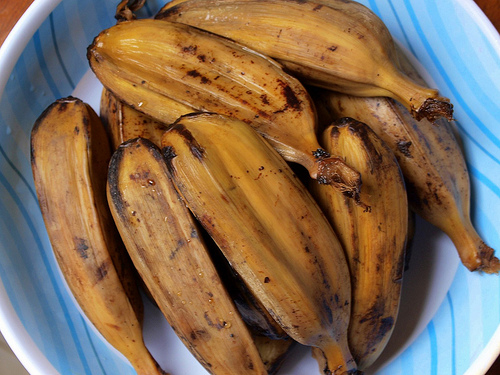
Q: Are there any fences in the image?
A: No, there are no fences.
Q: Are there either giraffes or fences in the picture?
A: No, there are no fences or giraffes.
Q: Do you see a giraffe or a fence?
A: No, there are no fences or giraffes.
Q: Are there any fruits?
A: Yes, there is a fruit.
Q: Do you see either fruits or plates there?
A: Yes, there is a fruit.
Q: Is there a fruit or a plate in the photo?
A: Yes, there is a fruit.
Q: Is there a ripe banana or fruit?
A: Yes, there is a ripe fruit.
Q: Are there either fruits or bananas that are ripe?
A: Yes, the fruit is ripe.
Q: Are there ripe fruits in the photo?
A: Yes, there is a ripe fruit.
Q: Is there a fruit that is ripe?
A: Yes, there is a fruit that is ripe.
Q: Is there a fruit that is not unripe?
A: Yes, there is an ripe fruit.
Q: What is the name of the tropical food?
A: The food is a fruit.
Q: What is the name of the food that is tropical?
A: The food is a fruit.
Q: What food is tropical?
A: The food is a fruit.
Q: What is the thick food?
A: The food is plantains.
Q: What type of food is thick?
A: The food is plantains.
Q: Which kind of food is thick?
A: The food is plantains.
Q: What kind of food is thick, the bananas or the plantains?
A: The plantains is thick.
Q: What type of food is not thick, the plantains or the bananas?
A: The bananas is not thick.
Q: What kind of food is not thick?
A: The food is bananas.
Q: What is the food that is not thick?
A: The food is bananas.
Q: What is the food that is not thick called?
A: The food is bananas.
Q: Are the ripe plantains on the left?
A: Yes, the plantains are on the left of the image.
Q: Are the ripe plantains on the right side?
A: No, the plantains are on the left of the image.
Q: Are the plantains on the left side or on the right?
A: The plantains are on the left of the image.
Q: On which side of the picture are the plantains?
A: The plantains are on the left of the image.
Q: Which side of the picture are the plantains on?
A: The plantains are on the left of the image.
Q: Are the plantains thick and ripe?
A: Yes, the plantains are thick and ripe.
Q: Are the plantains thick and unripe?
A: No, the plantains are thick but ripe.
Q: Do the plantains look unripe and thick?
A: No, the plantains are thick but ripe.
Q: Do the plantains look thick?
A: Yes, the plantains are thick.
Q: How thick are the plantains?
A: The plantains are thick.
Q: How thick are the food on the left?
A: The plantains are thick.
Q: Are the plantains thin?
A: No, the plantains are thick.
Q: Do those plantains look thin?
A: No, the plantains are thick.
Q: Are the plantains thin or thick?
A: The plantains are thick.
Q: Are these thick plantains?
A: Yes, these are thick plantains.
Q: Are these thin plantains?
A: No, these are thick plantains.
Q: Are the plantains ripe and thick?
A: Yes, the plantains are ripe and thick.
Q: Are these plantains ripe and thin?
A: No, the plantains are ripe but thick.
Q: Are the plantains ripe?
A: Yes, the plantains are ripe.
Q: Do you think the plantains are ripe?
A: Yes, the plantains are ripe.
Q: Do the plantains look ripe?
A: Yes, the plantains are ripe.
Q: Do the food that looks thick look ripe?
A: Yes, the plantains are ripe.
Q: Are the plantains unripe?
A: No, the plantains are ripe.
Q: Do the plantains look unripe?
A: No, the plantains are ripe.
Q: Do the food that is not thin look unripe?
A: No, the plantains are ripe.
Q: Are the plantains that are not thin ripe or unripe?
A: The plantains are ripe.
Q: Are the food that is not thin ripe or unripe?
A: The plantains are ripe.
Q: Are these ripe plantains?
A: Yes, these are ripe plantains.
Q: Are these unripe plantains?
A: No, these are ripe plantains.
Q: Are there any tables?
A: Yes, there is a table.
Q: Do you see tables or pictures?
A: Yes, there is a table.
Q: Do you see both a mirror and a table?
A: No, there is a table but no mirrors.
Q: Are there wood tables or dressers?
A: Yes, there is a wood table.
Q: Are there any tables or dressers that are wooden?
A: Yes, the table is wooden.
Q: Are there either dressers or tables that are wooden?
A: Yes, the table is wooden.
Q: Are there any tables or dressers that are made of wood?
A: Yes, the table is made of wood.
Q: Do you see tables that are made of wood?
A: Yes, there is a table that is made of wood.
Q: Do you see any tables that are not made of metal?
A: Yes, there is a table that is made of wood.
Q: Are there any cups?
A: No, there are no cups.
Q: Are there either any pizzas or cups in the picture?
A: No, there are no cups or pizzas.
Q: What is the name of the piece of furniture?
A: The piece of furniture is a table.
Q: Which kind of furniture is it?
A: The piece of furniture is a table.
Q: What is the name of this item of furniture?
A: This is a table.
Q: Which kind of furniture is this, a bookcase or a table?
A: This is a table.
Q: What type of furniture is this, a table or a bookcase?
A: This is a table.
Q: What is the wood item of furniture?
A: The piece of furniture is a table.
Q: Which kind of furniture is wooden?
A: The furniture is a table.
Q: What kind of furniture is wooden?
A: The furniture is a table.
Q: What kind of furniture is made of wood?
A: The furniture is a table.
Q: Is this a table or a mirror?
A: This is a table.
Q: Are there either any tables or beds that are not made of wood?
A: No, there is a table but it is made of wood.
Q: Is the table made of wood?
A: Yes, the table is made of wood.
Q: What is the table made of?
A: The table is made of wood.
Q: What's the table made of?
A: The table is made of wood.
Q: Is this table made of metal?
A: No, the table is made of wood.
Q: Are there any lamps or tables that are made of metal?
A: No, there is a table but it is made of wood.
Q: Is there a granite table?
A: No, there is a table but it is made of wood.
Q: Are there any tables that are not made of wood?
A: No, there is a table but it is made of wood.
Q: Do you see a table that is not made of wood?
A: No, there is a table but it is made of wood.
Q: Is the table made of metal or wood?
A: The table is made of wood.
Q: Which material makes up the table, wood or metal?
A: The table is made of wood.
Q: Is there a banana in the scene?
A: Yes, there are bananas.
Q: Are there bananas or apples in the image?
A: Yes, there are bananas.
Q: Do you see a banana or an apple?
A: Yes, there are bananas.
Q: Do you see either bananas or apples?
A: Yes, there are bananas.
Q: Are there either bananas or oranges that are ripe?
A: Yes, the bananas are ripe.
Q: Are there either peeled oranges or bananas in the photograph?
A: Yes, there are peeled bananas.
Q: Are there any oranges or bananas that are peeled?
A: Yes, the bananas are peeled.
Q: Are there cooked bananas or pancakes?
A: Yes, there are cooked bananas.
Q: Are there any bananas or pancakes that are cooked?
A: Yes, the bananas are cooked.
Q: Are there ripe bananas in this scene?
A: Yes, there are ripe bananas.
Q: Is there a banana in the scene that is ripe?
A: Yes, there are bananas that are ripe.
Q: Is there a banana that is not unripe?
A: Yes, there are ripe bananas.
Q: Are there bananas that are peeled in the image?
A: Yes, there are peeled bananas.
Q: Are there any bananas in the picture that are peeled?
A: Yes, there are bananas that are peeled.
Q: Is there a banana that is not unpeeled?
A: Yes, there are peeled bananas.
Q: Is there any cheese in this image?
A: No, there is no cheese.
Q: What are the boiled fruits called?
A: The fruits are bananas.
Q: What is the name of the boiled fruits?
A: The fruits are bananas.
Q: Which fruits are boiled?
A: The fruits are bananas.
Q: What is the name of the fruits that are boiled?
A: The fruits are bananas.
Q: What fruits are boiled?
A: The fruits are bananas.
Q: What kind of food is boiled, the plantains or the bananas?
A: The bananas is boiled.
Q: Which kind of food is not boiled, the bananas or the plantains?
A: The plantains is not boiled.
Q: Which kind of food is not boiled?
A: The food is plantains.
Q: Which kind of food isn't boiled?
A: The food is plantains.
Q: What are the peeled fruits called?
A: The fruits are bananas.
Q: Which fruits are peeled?
A: The fruits are bananas.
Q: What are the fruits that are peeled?
A: The fruits are bananas.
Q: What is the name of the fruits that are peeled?
A: The fruits are bananas.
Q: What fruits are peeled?
A: The fruits are bananas.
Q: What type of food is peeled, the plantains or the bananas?
A: The bananas is peeled.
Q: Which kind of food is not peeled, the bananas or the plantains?
A: The plantains is not peeled.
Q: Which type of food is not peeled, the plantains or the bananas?
A: The plantains is not peeled.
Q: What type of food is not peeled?
A: The food is plantains.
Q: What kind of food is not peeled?
A: The food is plantains.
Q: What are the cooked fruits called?
A: The fruits are bananas.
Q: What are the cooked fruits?
A: The fruits are bananas.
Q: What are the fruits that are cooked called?
A: The fruits are bananas.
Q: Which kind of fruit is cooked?
A: The fruit is bananas.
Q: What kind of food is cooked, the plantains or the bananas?
A: The bananas is cooked.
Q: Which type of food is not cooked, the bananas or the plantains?
A: The plantains is not cooked.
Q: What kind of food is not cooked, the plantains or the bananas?
A: The plantains is not cooked.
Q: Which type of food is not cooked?
A: The food is plantains.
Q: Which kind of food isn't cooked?
A: The food is plantains.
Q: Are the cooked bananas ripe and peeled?
A: Yes, the bananas are ripe and peeled.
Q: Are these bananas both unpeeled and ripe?
A: No, the bananas are ripe but peeled.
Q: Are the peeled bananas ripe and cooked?
A: Yes, the bananas are ripe and cooked.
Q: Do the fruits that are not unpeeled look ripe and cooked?
A: Yes, the bananas are ripe and cooked.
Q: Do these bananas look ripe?
A: Yes, the bananas are ripe.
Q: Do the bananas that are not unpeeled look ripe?
A: Yes, the bananas are ripe.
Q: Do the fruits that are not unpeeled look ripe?
A: Yes, the bananas are ripe.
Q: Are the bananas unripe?
A: No, the bananas are ripe.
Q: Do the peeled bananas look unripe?
A: No, the bananas are ripe.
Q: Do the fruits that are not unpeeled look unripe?
A: No, the bananas are ripe.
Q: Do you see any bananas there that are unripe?
A: No, there are bananas but they are ripe.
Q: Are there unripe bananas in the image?
A: No, there are bananas but they are ripe.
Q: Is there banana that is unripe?
A: No, there are bananas but they are ripe.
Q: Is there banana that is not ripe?
A: No, there are bananas but they are ripe.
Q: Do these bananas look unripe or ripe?
A: The bananas are ripe.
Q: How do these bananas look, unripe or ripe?
A: The bananas are ripe.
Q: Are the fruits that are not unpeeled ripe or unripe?
A: The bananas are ripe.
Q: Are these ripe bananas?
A: Yes, these are ripe bananas.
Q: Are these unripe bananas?
A: No, these are ripe bananas.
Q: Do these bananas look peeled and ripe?
A: Yes, the bananas are peeled and ripe.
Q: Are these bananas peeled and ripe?
A: Yes, the bananas are peeled and ripe.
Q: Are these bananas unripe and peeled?
A: No, the bananas are peeled but ripe.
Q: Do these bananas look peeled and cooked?
A: Yes, the bananas are peeled and cooked.